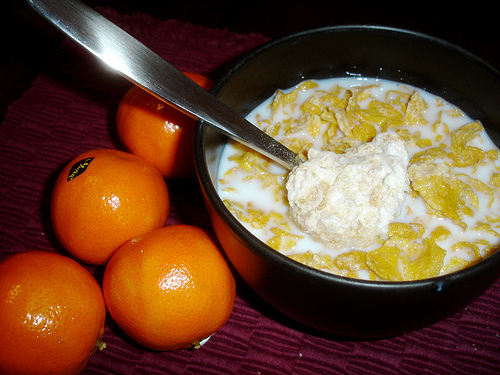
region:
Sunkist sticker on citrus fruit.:
[66, 151, 123, 203]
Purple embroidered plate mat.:
[220, 322, 284, 363]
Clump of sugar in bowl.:
[263, 32, 494, 253]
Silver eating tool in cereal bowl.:
[201, 36, 499, 216]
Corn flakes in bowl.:
[329, 78, 366, 126]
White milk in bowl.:
[243, 183, 263, 202]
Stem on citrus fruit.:
[81, 336, 109, 356]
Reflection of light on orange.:
[150, 260, 199, 300]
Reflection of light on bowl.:
[327, 19, 397, 45]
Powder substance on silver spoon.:
[259, 141, 297, 165]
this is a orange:
[88, 224, 240, 353]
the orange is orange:
[88, 211, 264, 362]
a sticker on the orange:
[57, 145, 125, 198]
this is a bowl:
[153, 12, 490, 367]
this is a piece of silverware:
[42, 14, 311, 186]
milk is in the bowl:
[228, 52, 497, 274]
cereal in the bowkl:
[257, 81, 445, 248]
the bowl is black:
[173, 25, 485, 359]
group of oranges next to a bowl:
[10, 0, 495, 374]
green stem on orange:
[80, 327, 110, 355]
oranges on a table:
[4, 77, 206, 363]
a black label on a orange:
[66, 150, 98, 186]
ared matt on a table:
[1, 79, 71, 184]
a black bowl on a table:
[187, 25, 499, 342]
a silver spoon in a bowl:
[30, 0, 328, 171]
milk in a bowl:
[244, 62, 495, 274]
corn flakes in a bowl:
[214, 52, 486, 293]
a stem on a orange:
[86, 323, 112, 359]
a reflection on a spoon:
[66, 2, 143, 95]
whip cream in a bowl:
[288, 120, 409, 240]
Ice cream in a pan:
[268, 130, 409, 241]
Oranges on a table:
[36, 136, 226, 353]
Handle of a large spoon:
[101, 7, 206, 139]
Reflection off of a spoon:
[85, 20, 130, 70]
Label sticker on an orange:
[59, 149, 99, 187]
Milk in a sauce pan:
[259, 98, 321, 131]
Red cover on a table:
[281, 342, 329, 367]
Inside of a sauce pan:
[394, 48, 443, 84]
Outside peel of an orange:
[116, 280, 150, 315]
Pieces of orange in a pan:
[431, 173, 456, 211]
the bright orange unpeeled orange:
[2, 256, 99, 373]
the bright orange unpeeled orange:
[101, 223, 237, 347]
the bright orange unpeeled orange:
[51, 150, 166, 261]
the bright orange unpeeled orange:
[117, 69, 217, 174]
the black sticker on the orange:
[65, 158, 98, 183]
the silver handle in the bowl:
[34, 3, 303, 168]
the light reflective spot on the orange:
[25, 305, 67, 334]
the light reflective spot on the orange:
[158, 265, 193, 292]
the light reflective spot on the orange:
[102, 193, 123, 211]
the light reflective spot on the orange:
[160, 118, 182, 135]